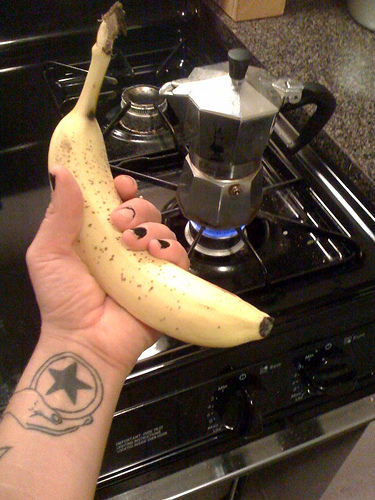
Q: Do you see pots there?
A: Yes, there is a pot.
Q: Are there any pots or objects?
A: Yes, there is a pot.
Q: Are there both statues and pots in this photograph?
A: No, there is a pot but no statues.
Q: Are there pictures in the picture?
A: No, there are no pictures.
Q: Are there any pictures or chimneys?
A: No, there are no pictures or chimneys.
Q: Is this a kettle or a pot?
A: This is a pot.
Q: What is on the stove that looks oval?
A: The pot is on the stove.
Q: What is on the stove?
A: The pot is on the stove.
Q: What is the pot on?
A: The pot is on the stove.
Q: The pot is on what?
A: The pot is on the stove.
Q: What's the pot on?
A: The pot is on the stove.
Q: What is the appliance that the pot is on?
A: The appliance is a stove.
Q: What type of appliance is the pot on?
A: The pot is on the stove.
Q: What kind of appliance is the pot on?
A: The pot is on the stove.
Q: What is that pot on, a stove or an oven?
A: The pot is on a stove.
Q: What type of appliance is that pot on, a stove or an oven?
A: The pot is on a stove.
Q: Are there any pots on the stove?
A: Yes, there is a pot on the stove.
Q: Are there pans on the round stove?
A: No, there is a pot on the stove.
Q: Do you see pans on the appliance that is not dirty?
A: No, there is a pot on the stove.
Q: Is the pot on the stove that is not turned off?
A: Yes, the pot is on the stove.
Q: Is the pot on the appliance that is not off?
A: Yes, the pot is on the stove.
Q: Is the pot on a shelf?
A: No, the pot is on the stove.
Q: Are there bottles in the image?
A: No, there are no bottles.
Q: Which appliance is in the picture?
A: The appliance is a stove.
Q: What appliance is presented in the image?
A: The appliance is a stove.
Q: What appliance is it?
A: The appliance is a stove.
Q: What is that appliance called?
A: This is a stove.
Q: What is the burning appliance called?
A: The appliance is a stove.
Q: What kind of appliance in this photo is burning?
A: The appliance is a stove.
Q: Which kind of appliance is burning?
A: The appliance is a stove.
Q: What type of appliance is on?
A: The appliance is a stove.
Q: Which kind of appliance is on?
A: The appliance is a stove.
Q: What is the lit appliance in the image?
A: The appliance is a stove.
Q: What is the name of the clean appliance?
A: The appliance is a stove.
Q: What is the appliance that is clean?
A: The appliance is a stove.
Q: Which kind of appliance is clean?
A: The appliance is a stove.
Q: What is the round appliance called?
A: The appliance is a stove.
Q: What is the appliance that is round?
A: The appliance is a stove.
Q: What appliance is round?
A: The appliance is a stove.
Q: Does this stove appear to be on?
A: Yes, the stove is on.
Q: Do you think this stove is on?
A: Yes, the stove is on.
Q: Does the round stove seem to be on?
A: Yes, the stove is on.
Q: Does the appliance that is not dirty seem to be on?
A: Yes, the stove is on.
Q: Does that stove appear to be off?
A: No, the stove is on.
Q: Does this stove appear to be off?
A: No, the stove is on.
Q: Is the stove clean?
A: Yes, the stove is clean.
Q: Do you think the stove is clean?
A: Yes, the stove is clean.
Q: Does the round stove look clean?
A: Yes, the stove is clean.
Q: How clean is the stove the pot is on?
A: The stove is clean.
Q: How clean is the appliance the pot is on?
A: The stove is clean.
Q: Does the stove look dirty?
A: No, the stove is clean.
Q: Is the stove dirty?
A: No, the stove is clean.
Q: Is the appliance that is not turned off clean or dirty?
A: The stove is clean.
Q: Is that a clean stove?
A: Yes, that is a clean stove.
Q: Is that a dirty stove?
A: No, that is a clean stove.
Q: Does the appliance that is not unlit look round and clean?
A: Yes, the stove is round and clean.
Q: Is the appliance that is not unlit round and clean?
A: Yes, the stove is round and clean.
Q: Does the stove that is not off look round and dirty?
A: No, the stove is round but clean.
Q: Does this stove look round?
A: Yes, the stove is round.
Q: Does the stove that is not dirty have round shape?
A: Yes, the stove is round.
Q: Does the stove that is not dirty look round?
A: Yes, the stove is round.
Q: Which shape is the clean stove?
A: The stove is round.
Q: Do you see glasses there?
A: No, there are no glasses.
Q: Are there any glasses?
A: No, there are no glasses.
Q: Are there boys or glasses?
A: No, there are no glasses or boys.